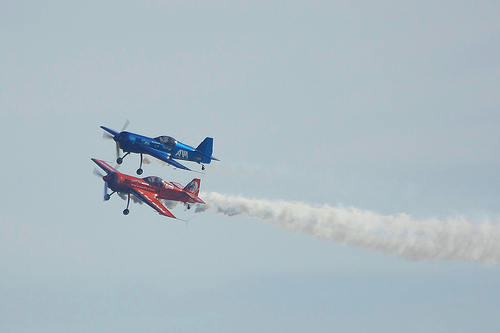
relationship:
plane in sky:
[90, 155, 205, 218] [0, 0, 499, 331]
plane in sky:
[96, 119, 221, 175] [0, 0, 499, 331]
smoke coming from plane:
[199, 182, 498, 264] [90, 155, 205, 218]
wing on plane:
[155, 151, 192, 171] [105, 124, 255, 208]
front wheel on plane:
[103, 190, 111, 202] [90, 155, 205, 218]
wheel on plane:
[123, 207, 130, 216] [90, 155, 205, 218]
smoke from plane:
[366, 216, 478, 256] [90, 155, 205, 218]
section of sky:
[270, 219, 342, 260] [228, 208, 483, 313]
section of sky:
[298, 267, 395, 305] [309, 256, 386, 286]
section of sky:
[10, 0, 85, 95] [11, 57, 69, 124]